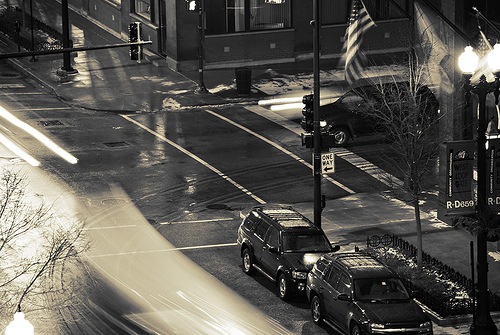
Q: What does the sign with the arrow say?
A: One way.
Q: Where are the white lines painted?
A: On the road.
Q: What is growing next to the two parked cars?
A: A tree.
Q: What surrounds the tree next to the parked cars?
A: A low fence.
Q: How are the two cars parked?
A: One behind the other.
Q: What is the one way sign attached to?
A: A pole.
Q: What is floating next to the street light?
A: An American flag.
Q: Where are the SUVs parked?
A: On the side of the street.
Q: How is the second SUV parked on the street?
A: Very close to the SUV parked upfront.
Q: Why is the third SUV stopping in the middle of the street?
A: Because the SUV is at an intersection.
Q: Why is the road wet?
A: Because light snow was falling earlier.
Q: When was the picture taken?
A: Late in the evening.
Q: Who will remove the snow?
A: The people in charge of removing snow.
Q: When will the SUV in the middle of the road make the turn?
A: Once the upcoming car is gone.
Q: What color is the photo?
A: Black and white.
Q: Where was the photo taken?
A: The street.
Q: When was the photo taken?
A: Nighttime.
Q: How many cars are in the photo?
A: Three.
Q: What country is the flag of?
A: America.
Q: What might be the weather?
A: Rainy.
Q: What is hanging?
A: Traffic light.